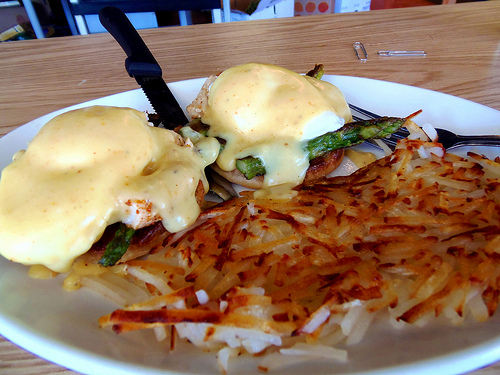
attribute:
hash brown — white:
[275, 337, 353, 367]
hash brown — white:
[342, 304, 386, 347]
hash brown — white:
[340, 294, 367, 337]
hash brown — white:
[219, 324, 285, 350]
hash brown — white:
[217, 340, 240, 372]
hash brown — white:
[81, 271, 130, 312]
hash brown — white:
[83, 271, 137, 309]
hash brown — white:
[114, 259, 179, 302]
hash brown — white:
[465, 289, 490, 323]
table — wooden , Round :
[0, 0, 499, 372]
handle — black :
[97, 1, 161, 74]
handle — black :
[97, 5, 161, 78]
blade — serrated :
[134, 70, 190, 128]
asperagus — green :
[236, 114, 403, 179]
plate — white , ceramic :
[0, 72, 500, 372]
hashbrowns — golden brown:
[97, 134, 497, 364]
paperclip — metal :
[377, 49, 427, 60]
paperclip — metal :
[351, 40, 369, 62]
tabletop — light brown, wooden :
[3, 1, 497, 372]